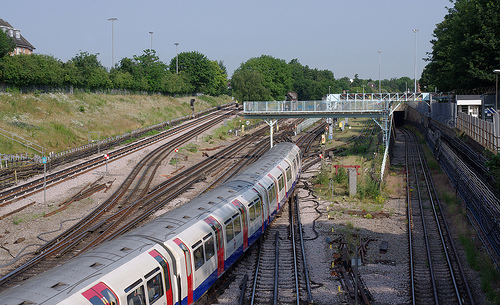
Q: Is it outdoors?
A: Yes, it is outdoors.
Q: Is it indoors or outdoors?
A: It is outdoors.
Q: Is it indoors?
A: No, it is outdoors.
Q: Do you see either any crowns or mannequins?
A: No, there are no mannequins or crowns.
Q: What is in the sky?
A: The clouds are in the sky.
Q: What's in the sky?
A: The clouds are in the sky.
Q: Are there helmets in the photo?
A: No, there are no helmets.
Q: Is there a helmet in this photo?
A: No, there are no helmets.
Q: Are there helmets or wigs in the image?
A: No, there are no helmets or wigs.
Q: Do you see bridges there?
A: Yes, there is a bridge.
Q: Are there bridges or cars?
A: Yes, there is a bridge.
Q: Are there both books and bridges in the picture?
A: No, there is a bridge but no books.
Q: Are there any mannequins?
A: No, there are no mannequins.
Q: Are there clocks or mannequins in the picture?
A: No, there are no mannequins or clocks.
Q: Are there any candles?
A: No, there are no candles.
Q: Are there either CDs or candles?
A: No, there are no candles or cds.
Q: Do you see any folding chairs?
A: No, there are no folding chairs.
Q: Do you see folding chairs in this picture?
A: No, there are no folding chairs.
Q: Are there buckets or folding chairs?
A: No, there are no folding chairs or buckets.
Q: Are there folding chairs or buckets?
A: No, there are no folding chairs or buckets.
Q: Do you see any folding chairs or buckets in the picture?
A: No, there are no folding chairs or buckets.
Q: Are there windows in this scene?
A: Yes, there is a window.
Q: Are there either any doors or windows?
A: Yes, there is a window.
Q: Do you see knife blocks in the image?
A: No, there are no knife blocks.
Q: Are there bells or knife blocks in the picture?
A: No, there are no knife blocks or bells.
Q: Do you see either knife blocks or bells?
A: No, there are no knife blocks or bells.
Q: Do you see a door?
A: Yes, there is a door.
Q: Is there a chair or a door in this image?
A: Yes, there is a door.